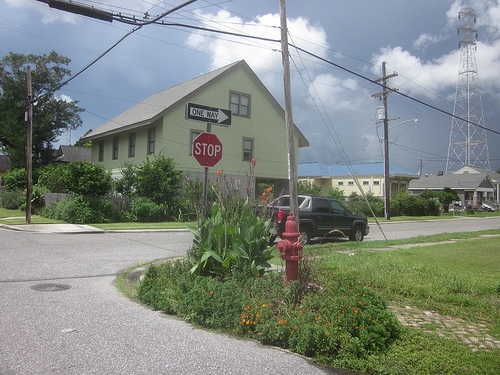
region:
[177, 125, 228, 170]
Stop sign in the photo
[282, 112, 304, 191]
A pole in the photo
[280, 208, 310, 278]
A red hydrant in the photo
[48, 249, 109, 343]
A road with tarmac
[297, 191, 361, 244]
A black car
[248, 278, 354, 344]
Flowers on the roadside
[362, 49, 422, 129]
Power poles in the photo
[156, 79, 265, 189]
A house in the photo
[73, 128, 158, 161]
Windows in the photo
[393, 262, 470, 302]
Grass in the field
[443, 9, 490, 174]
an electric pylon next to a house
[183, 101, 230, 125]
a black and white one way sign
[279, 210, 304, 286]
a red fire hydrant on the grass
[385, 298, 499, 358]
a sidewalk filled with grass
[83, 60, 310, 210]
a yellow house with a triangular roof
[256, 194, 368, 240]
a lack car parked on the street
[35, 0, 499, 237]
electrical wires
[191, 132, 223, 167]
a red and white stop sign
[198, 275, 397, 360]
a bush with orange flowers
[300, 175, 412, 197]
a one story building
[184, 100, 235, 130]
A black and white street sign.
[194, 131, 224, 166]
An octogonal sign.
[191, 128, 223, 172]
A red and white stop sign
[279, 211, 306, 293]
A red fire hydrant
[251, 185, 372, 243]
A black truck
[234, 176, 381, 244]
A vehicle on the road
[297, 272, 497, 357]
Beige colored stones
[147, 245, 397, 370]
Small shrubs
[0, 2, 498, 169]
A blue sky with large white clouds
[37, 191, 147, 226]
A wooden fence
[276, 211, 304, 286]
the fire hydrant in the grass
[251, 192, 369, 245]
the truck parked on the street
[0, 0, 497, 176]
the white clouds in the blue sky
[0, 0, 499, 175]
the blue sky with white clouds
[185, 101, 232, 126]
the ONE WAY sign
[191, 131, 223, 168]
the sign under the ONE WAY sign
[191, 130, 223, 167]
the red and white STOP sign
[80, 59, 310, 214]
the large house on the corner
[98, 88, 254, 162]
the windows on the house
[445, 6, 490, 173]
the tower for high voltage power lines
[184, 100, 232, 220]
Post has street signs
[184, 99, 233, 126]
rectangular one way sign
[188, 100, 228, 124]
White arrow with one way printed on it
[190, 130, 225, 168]
Red and white sign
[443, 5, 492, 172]
Tall tower post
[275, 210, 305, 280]
Red fire hydrant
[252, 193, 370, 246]
Black truck parked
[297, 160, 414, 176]
A blue roof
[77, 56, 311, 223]
Big green house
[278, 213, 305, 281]
a red fire hydrant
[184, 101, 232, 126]
a black and white sign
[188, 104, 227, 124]
a white arrow on a sign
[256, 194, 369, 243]
a black truck is parked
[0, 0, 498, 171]
sky is filled with huge clouds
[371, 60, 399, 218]
a wooden brown electrical pole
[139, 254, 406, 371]
bushes are lush and green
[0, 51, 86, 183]
leaves on the tree are green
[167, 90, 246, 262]
stop sign and one way sign on pole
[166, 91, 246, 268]
stop sign and one way sign on pole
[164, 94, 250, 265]
stop sign and one way sign on pole